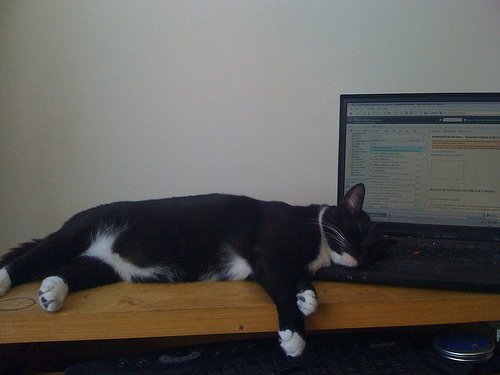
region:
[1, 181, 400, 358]
black and white cat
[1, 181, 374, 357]
cat laying on desk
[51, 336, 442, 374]
black computer key board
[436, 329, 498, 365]
blue and silver computer mouse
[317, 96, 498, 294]
black laptop on desk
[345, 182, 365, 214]
black ear of cat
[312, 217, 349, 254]
white whiskers on cat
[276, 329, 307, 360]
white paw on cat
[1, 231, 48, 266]
black tail of cat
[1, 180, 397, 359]
cat sleeping on desk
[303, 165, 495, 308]
Cat resting head on laptop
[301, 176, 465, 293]
Cat resting head on keyboard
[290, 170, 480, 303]
Cat sleeping on computer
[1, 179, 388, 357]
Cat sleeping on desk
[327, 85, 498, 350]
Laptop sitting on desk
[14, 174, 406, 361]
Cat sleeping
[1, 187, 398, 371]
Cat with leg hanging over table edge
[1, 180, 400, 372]
Black cat with white paws and stomach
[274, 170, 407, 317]
Cat with white whiskers sleeping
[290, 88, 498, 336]
Cat sleeping on running laptop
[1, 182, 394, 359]
Cat laying on the side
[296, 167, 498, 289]
Head on a keyboard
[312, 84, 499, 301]
Laptop with flap open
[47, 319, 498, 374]
Black desktop computer keyboard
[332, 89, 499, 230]
Laptop screen with a dispay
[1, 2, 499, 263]
Smooth white colored wall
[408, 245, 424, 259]
Small round red button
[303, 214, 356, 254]
White colored curved whiskers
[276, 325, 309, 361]
White colored paw of a cat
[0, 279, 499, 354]
Brown wooden top of a desk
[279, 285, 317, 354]
white paws on the cat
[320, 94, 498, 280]
the laptop is open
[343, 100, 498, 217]
the computer screen is on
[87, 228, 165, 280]
white fur on the cat's belly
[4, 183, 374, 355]
the cat is sleeping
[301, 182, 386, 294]
cat's head on the laptop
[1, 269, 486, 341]
a wood desk top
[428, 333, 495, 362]
a metal can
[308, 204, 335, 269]
the cat's neck is white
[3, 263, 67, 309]
the back paws are white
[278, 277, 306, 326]
;part of a paw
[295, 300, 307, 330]
[part of a paw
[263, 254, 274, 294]
part fo a hand